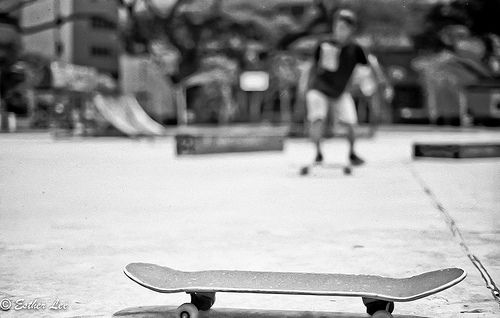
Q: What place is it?
A: It is a street.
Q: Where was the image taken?
A: It was taken at the street.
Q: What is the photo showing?
A: It is showing a street.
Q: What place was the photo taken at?
A: It was taken at the street.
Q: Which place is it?
A: It is a street.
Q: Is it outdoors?
A: Yes, it is outdoors.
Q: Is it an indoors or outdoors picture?
A: It is outdoors.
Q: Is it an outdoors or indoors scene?
A: It is outdoors.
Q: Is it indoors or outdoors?
A: It is outdoors.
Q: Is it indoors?
A: No, it is outdoors.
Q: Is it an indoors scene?
A: No, it is outdoors.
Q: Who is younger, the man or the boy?
A: The boy is younger than the man.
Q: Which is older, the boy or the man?
A: The man is older than the boy.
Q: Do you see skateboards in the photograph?
A: Yes, there is a skateboard.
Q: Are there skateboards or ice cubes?
A: Yes, there is a skateboard.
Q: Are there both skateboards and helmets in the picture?
A: No, there is a skateboard but no helmets.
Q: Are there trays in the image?
A: No, there are no trays.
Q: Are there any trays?
A: No, there are no trays.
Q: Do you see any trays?
A: No, there are no trays.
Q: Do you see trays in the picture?
A: No, there are no trays.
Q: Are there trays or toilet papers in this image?
A: No, there are no trays or toilet papers.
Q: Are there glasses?
A: No, there are no glasses.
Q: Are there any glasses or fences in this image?
A: No, there are no glasses or fences.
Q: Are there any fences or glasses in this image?
A: No, there are no glasses or fences.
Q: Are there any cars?
A: No, there are no cars.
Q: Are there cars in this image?
A: No, there are no cars.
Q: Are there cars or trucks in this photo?
A: No, there are no cars or trucks.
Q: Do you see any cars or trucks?
A: No, there are no cars or trucks.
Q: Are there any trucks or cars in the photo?
A: No, there are no cars or trucks.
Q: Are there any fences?
A: No, there are no fences.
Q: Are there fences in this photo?
A: No, there are no fences.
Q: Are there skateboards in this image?
A: Yes, there is a skateboard.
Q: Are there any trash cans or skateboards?
A: Yes, there is a skateboard.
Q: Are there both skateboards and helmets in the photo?
A: No, there is a skateboard but no helmets.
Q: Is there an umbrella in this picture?
A: No, there are no umbrellas.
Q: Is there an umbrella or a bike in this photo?
A: No, there are no umbrellas or bikes.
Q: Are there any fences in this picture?
A: No, there are no fences.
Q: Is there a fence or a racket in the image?
A: No, there are no fences or rackets.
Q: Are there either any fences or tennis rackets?
A: No, there are no fences or tennis rackets.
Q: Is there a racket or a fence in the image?
A: No, there are no fences or rackets.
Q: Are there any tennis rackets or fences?
A: No, there are no fences or tennis rackets.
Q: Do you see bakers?
A: No, there are no bakers.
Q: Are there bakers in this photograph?
A: No, there are no bakers.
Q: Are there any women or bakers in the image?
A: No, there are no bakers or women.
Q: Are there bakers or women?
A: No, there are no bakers or women.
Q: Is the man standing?
A: Yes, the man is standing.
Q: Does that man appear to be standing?
A: Yes, the man is standing.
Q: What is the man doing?
A: The man is standing.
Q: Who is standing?
A: The man is standing.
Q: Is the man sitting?
A: No, the man is standing.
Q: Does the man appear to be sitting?
A: No, the man is standing.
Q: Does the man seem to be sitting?
A: No, the man is standing.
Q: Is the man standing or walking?
A: The man is standing.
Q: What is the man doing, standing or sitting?
A: The man is standing.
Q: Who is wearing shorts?
A: The man is wearing shorts.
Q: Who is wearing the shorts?
A: The man is wearing shorts.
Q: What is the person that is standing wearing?
A: The man is wearing shorts.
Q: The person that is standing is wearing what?
A: The man is wearing shorts.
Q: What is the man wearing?
A: The man is wearing shorts.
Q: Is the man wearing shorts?
A: Yes, the man is wearing shorts.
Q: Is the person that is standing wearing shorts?
A: Yes, the man is wearing shorts.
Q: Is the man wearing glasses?
A: No, the man is wearing shorts.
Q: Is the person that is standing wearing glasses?
A: No, the man is wearing shorts.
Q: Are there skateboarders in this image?
A: Yes, there is a skateboarder.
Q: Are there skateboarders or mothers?
A: Yes, there is a skateboarder.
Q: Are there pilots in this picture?
A: No, there are no pilots.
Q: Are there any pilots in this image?
A: No, there are no pilots.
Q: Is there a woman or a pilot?
A: No, there are no pilots or women.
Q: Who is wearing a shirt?
A: The skateboarder is wearing a shirt.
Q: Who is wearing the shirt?
A: The skateboarder is wearing a shirt.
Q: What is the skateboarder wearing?
A: The skateboarder is wearing a shirt.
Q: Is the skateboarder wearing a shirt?
A: Yes, the skateboarder is wearing a shirt.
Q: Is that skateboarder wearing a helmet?
A: No, the skateboarder is wearing a shirt.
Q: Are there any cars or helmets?
A: No, there are no cars or helmets.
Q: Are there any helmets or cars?
A: No, there are no cars or helmets.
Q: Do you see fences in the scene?
A: No, there are no fences.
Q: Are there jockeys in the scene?
A: No, there are no jockeys.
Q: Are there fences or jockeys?
A: No, there are no jockeys or fences.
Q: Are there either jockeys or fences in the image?
A: No, there are no jockeys or fences.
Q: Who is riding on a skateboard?
A: The boy is riding on a skateboard.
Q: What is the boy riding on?
A: The boy is riding on a skateboard.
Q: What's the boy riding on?
A: The boy is riding on a skateboard.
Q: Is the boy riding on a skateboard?
A: Yes, the boy is riding on a skateboard.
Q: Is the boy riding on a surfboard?
A: No, the boy is riding on a skateboard.